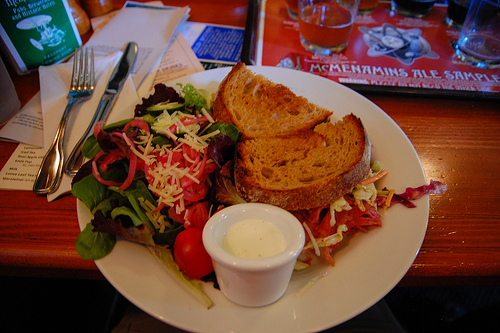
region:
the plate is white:
[72, 103, 399, 288]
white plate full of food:
[91, 71, 403, 311]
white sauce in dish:
[186, 207, 348, 332]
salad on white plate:
[104, 82, 221, 259]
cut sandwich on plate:
[213, 66, 398, 266]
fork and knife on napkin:
[47, 38, 121, 208]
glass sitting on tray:
[434, 11, 496, 112]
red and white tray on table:
[277, 25, 478, 124]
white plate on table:
[113, 52, 471, 307]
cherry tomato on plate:
[161, 224, 210, 304]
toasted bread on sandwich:
[205, 70, 381, 260]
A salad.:
[76, 78, 219, 269]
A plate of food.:
[75, 65, 450, 320]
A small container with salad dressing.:
[205, 195, 300, 307]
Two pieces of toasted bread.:
[215, 55, 365, 200]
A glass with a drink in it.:
[285, 0, 361, 60]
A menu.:
[230, 0, 495, 97]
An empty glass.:
[445, 0, 495, 60]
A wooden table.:
[415, 95, 495, 295]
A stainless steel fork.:
[30, 36, 95, 201]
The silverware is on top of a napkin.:
[35, 35, 138, 201]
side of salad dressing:
[208, 215, 293, 306]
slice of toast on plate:
[241, 137, 366, 184]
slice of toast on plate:
[214, 71, 317, 121]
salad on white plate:
[98, 87, 395, 309]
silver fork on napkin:
[68, 56, 85, 208]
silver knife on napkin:
[111, 40, 136, 114]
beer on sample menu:
[300, 0, 358, 58]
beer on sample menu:
[451, 0, 497, 73]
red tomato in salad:
[183, 236, 212, 281]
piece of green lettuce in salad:
[68, 227, 113, 262]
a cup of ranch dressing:
[198, 202, 306, 308]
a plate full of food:
[75, 63, 429, 332]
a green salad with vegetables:
[70, 81, 237, 307]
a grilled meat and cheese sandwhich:
[212, 58, 389, 243]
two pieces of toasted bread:
[216, 62, 367, 199]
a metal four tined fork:
[32, 49, 99, 191]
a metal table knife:
[61, 39, 138, 177]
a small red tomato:
[174, 228, 214, 278]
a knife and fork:
[32, 41, 139, 196]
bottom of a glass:
[295, 1, 355, 51]